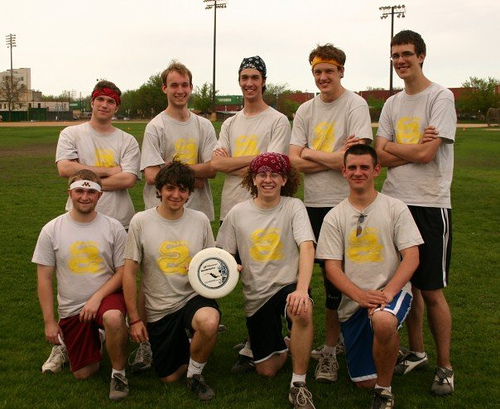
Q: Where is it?
A: This is at the lawn.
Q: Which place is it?
A: It is a lawn.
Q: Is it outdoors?
A: Yes, it is outdoors.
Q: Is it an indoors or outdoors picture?
A: It is outdoors.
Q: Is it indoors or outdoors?
A: It is outdoors.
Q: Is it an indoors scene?
A: No, it is outdoors.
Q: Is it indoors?
A: No, it is outdoors.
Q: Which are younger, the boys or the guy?
A: The boys are younger than the guy.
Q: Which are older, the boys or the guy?
A: The guy are older than the boys.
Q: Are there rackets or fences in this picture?
A: No, there are no fences or rackets.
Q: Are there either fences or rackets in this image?
A: No, there are no fences or rackets.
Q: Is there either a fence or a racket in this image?
A: No, there are no fences or rackets.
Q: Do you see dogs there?
A: No, there are no dogs.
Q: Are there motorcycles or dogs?
A: No, there are no dogs or motorcycles.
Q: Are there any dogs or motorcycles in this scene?
A: No, there are no dogs or motorcycles.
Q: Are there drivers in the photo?
A: No, there are no drivers.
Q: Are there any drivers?
A: No, there are no drivers.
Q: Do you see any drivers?
A: No, there are no drivers.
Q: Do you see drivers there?
A: No, there are no drivers.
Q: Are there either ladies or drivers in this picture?
A: No, there are no drivers or ladies.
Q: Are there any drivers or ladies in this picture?
A: No, there are no drivers or ladies.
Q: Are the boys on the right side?
A: Yes, the boys are on the right of the image.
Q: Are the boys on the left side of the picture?
A: No, the boys are on the right of the image.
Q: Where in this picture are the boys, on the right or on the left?
A: The boys are on the right of the image.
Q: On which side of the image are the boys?
A: The boys are on the right of the image.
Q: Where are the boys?
A: The boys are in the grass.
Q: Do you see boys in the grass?
A: Yes, there are boys in the grass.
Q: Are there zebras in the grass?
A: No, there are boys in the grass.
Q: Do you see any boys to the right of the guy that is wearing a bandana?
A: Yes, there are boys to the right of the guy.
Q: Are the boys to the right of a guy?
A: Yes, the boys are to the right of a guy.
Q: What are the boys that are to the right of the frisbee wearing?
A: The boys are wearing a bandana.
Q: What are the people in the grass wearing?
A: The boys are wearing a bandana.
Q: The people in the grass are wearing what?
A: The boys are wearing a bandana.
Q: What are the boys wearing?
A: The boys are wearing a bandana.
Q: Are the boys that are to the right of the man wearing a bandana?
A: Yes, the boys are wearing a bandana.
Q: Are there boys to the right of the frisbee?
A: Yes, there are boys to the right of the frisbee.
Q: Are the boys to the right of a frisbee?
A: Yes, the boys are to the right of a frisbee.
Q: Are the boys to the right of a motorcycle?
A: No, the boys are to the right of a frisbee.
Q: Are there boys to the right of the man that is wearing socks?
A: Yes, there are boys to the right of the man.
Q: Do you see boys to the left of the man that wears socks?
A: No, the boys are to the right of the man.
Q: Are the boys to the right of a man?
A: Yes, the boys are to the right of a man.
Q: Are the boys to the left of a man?
A: No, the boys are to the right of a man.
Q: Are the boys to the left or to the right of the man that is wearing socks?
A: The boys are to the right of the man.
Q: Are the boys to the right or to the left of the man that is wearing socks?
A: The boys are to the right of the man.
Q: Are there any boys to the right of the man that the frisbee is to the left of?
A: Yes, there are boys to the right of the man.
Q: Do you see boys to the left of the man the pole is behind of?
A: No, the boys are to the right of the man.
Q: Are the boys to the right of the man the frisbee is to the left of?
A: Yes, the boys are to the right of the man.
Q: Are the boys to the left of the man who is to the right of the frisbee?
A: No, the boys are to the right of the man.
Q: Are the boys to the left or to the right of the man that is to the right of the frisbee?
A: The boys are to the right of the man.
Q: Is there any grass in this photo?
A: Yes, there is grass.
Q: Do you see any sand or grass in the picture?
A: Yes, there is grass.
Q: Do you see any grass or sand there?
A: Yes, there is grass.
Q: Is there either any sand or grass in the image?
A: Yes, there is grass.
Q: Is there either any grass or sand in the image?
A: Yes, there is grass.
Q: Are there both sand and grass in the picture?
A: No, there is grass but no sand.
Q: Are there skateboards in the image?
A: No, there are no skateboards.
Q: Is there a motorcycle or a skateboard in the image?
A: No, there are no skateboards or motorcycles.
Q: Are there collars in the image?
A: Yes, there is a collar.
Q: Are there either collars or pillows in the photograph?
A: Yes, there is a collar.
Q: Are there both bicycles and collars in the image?
A: No, there is a collar but no bicycles.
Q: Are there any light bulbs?
A: No, there are no light bulbs.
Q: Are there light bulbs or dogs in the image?
A: No, there are no light bulbs or dogs.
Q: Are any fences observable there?
A: No, there are no fences.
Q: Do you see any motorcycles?
A: No, there are no motorcycles.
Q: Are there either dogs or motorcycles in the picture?
A: No, there are no motorcycles or dogs.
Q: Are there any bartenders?
A: No, there are no bartenders.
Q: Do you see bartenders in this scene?
A: No, there are no bartenders.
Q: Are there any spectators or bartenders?
A: No, there are no bartenders or spectators.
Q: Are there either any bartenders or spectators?
A: No, there are no bartenders or spectators.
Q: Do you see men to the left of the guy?
A: Yes, there is a man to the left of the guy.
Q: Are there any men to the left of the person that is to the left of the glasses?
A: Yes, there is a man to the left of the guy.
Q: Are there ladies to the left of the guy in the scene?
A: No, there is a man to the left of the guy.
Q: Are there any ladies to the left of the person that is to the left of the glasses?
A: No, there is a man to the left of the guy.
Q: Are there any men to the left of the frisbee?
A: Yes, there is a man to the left of the frisbee.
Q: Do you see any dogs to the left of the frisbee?
A: No, there is a man to the left of the frisbee.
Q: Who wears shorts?
A: The man wears shorts.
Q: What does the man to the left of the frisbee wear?
A: The man wears shorts.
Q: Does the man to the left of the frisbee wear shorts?
A: Yes, the man wears shorts.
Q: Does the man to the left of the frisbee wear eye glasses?
A: No, the man wears shorts.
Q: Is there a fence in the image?
A: No, there are no fences.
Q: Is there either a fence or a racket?
A: No, there are no fences or rackets.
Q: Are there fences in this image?
A: No, there are no fences.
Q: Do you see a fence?
A: No, there are no fences.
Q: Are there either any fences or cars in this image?
A: No, there are no fences or cars.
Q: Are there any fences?
A: No, there are no fences.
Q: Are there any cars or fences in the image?
A: No, there are no fences or cars.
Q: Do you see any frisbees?
A: Yes, there is a frisbee.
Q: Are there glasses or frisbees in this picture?
A: Yes, there is a frisbee.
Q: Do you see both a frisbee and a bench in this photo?
A: No, there is a frisbee but no benches.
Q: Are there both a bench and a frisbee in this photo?
A: No, there is a frisbee but no benches.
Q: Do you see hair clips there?
A: No, there are no hair clips.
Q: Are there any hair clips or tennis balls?
A: No, there are no hair clips or tennis balls.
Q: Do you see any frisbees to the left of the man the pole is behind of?
A: Yes, there is a frisbee to the left of the man.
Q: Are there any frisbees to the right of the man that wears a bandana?
A: No, the frisbee is to the left of the man.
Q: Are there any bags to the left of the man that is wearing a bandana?
A: No, there is a frisbee to the left of the man.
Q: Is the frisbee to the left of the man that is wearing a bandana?
A: Yes, the frisbee is to the left of the man.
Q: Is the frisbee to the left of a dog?
A: No, the frisbee is to the left of the man.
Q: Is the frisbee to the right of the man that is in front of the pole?
A: No, the frisbee is to the left of the man.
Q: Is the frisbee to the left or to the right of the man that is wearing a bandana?
A: The frisbee is to the left of the man.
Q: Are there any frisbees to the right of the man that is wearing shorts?
A: Yes, there is a frisbee to the right of the man.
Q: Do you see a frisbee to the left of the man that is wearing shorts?
A: No, the frisbee is to the right of the man.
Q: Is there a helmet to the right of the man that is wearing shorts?
A: No, there is a frisbee to the right of the man.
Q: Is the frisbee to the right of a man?
A: Yes, the frisbee is to the right of a man.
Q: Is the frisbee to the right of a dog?
A: No, the frisbee is to the right of a man.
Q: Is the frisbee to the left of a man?
A: No, the frisbee is to the right of a man.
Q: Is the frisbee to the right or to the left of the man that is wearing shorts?
A: The frisbee is to the right of the man.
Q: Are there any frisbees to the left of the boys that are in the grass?
A: Yes, there is a frisbee to the left of the boys.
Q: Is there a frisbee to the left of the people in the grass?
A: Yes, there is a frisbee to the left of the boys.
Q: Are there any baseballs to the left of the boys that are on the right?
A: No, there is a frisbee to the left of the boys.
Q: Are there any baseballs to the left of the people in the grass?
A: No, there is a frisbee to the left of the boys.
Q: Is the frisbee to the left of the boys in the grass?
A: Yes, the frisbee is to the left of the boys.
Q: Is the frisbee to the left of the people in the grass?
A: Yes, the frisbee is to the left of the boys.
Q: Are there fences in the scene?
A: No, there are no fences.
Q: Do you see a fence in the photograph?
A: No, there are no fences.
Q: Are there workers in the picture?
A: No, there are no workers.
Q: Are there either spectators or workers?
A: No, there are no workers or spectators.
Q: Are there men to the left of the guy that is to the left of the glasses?
A: Yes, there is a man to the left of the guy.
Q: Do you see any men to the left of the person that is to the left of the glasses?
A: Yes, there is a man to the left of the guy.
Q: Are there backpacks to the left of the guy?
A: No, there is a man to the left of the guy.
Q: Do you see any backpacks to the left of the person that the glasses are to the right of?
A: No, there is a man to the left of the guy.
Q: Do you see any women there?
A: No, there are no women.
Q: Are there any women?
A: No, there are no women.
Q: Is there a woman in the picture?
A: No, there are no women.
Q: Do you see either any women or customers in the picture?
A: No, there are no women or customers.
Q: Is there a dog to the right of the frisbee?
A: No, there is a man to the right of the frisbee.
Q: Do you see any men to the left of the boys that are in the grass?
A: Yes, there is a man to the left of the boys.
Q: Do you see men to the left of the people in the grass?
A: Yes, there is a man to the left of the boys.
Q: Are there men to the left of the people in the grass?
A: Yes, there is a man to the left of the boys.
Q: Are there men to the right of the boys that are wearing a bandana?
A: No, the man is to the left of the boys.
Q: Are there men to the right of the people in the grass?
A: No, the man is to the left of the boys.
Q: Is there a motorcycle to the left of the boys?
A: No, there is a man to the left of the boys.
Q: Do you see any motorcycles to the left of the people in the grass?
A: No, there is a man to the left of the boys.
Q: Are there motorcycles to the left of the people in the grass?
A: No, there is a man to the left of the boys.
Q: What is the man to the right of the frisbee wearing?
A: The man is wearing a bandana.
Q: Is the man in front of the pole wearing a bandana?
A: Yes, the man is wearing a bandana.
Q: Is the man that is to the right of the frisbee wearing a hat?
A: No, the man is wearing a bandana.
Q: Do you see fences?
A: No, there are no fences.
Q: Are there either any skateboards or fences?
A: No, there are no fences or skateboards.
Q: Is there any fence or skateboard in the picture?
A: No, there are no fences or skateboards.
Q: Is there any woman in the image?
A: No, there are no women.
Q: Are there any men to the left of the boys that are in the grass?
A: Yes, there is a man to the left of the boys.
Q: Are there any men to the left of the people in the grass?
A: Yes, there is a man to the left of the boys.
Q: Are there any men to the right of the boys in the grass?
A: No, the man is to the left of the boys.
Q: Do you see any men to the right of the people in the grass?
A: No, the man is to the left of the boys.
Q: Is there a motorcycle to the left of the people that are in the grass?
A: No, there is a man to the left of the boys.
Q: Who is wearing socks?
A: The man is wearing socks.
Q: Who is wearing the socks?
A: The man is wearing socks.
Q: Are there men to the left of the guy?
A: Yes, there is a man to the left of the guy.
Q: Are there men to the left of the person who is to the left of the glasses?
A: Yes, there is a man to the left of the guy.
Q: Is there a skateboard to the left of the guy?
A: No, there is a man to the left of the guy.